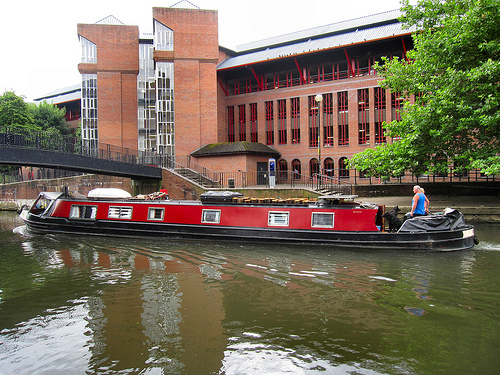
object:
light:
[315, 94, 323, 103]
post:
[318, 101, 322, 185]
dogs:
[389, 204, 402, 216]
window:
[337, 89, 350, 147]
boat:
[15, 187, 479, 254]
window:
[237, 104, 247, 143]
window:
[289, 96, 301, 144]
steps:
[203, 185, 215, 188]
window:
[147, 207, 166, 221]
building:
[28, 0, 499, 188]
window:
[264, 99, 275, 145]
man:
[403, 185, 430, 222]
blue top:
[410, 193, 426, 215]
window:
[248, 102, 259, 143]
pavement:
[354, 182, 496, 212]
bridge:
[0, 127, 163, 180]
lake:
[0, 199, 500, 375]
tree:
[338, 2, 497, 185]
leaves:
[384, 134, 387, 136]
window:
[320, 89, 335, 151]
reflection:
[24, 235, 399, 372]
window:
[310, 211, 335, 228]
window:
[201, 209, 221, 224]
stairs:
[168, 155, 222, 190]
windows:
[29, 193, 54, 216]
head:
[413, 185, 421, 194]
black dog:
[381, 211, 404, 234]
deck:
[374, 210, 474, 236]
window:
[268, 210, 290, 228]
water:
[0, 210, 499, 373]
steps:
[331, 192, 344, 197]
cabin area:
[16, 185, 68, 234]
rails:
[168, 159, 220, 183]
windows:
[150, 100, 155, 106]